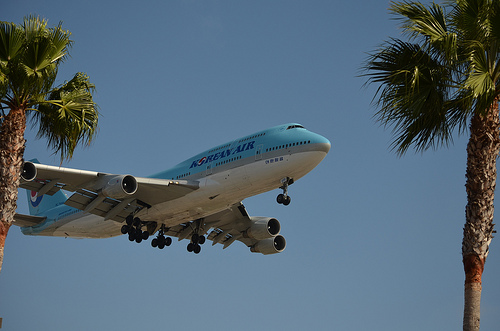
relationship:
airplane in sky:
[14, 119, 336, 257] [4, 4, 500, 330]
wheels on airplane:
[272, 192, 295, 205] [14, 119, 336, 257]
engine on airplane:
[98, 174, 141, 197] [14, 119, 336, 257]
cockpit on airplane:
[278, 118, 313, 134] [14, 119, 336, 257]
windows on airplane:
[240, 127, 272, 143] [14, 119, 336, 257]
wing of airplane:
[18, 159, 200, 228] [14, 119, 336, 257]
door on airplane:
[254, 145, 267, 159] [14, 119, 336, 257]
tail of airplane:
[23, 156, 69, 209] [14, 119, 336, 257]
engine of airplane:
[98, 174, 141, 197] [14, 119, 336, 257]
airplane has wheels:
[14, 119, 336, 257] [272, 192, 295, 205]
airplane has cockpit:
[14, 119, 336, 257] [278, 118, 313, 134]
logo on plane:
[185, 135, 263, 174] [14, 119, 336, 257]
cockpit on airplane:
[283, 120, 309, 138] [14, 119, 336, 257]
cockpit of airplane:
[278, 118, 313, 134] [14, 119, 336, 257]